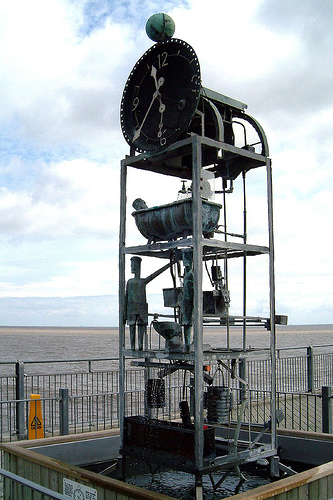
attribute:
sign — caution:
[27, 393, 44, 439]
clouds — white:
[0, 1, 332, 291]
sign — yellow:
[23, 396, 62, 448]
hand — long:
[128, 72, 166, 142]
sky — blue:
[1, 0, 331, 297]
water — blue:
[0, 324, 332, 435]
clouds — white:
[5, 0, 119, 292]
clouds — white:
[188, 3, 332, 322]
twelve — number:
[155, 50, 171, 68]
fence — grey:
[28, 339, 131, 447]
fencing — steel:
[0, 373, 117, 436]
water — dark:
[0, 295, 331, 325]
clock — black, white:
[120, 39, 201, 154]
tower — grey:
[96, 10, 297, 494]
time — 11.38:
[118, 36, 201, 153]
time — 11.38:
[91, 20, 225, 181]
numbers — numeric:
[121, 47, 199, 154]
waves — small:
[271, 353, 327, 379]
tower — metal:
[105, 19, 283, 453]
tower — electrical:
[119, 12, 277, 463]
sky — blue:
[39, 29, 92, 174]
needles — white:
[128, 66, 167, 142]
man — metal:
[126, 251, 181, 350]